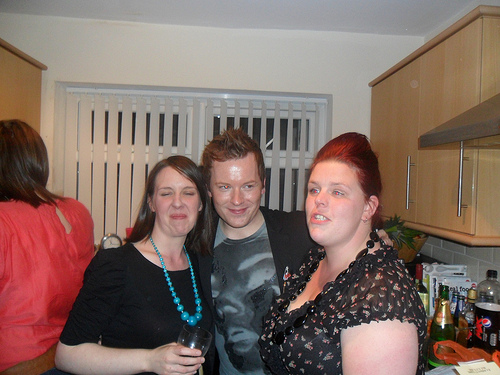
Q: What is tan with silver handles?
A: Cabinets.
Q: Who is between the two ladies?
A: Young man.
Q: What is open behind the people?
A: Blinds.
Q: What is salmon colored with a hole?
A: Blouse.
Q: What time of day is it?
A: Night.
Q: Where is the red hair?
A: On the woman.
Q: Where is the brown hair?
A: On the man.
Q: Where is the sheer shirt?
A: On the woman.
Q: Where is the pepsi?
A: On the counter.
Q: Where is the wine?
A: On the counter.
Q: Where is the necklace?
A: On the woman.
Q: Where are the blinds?
A: On the window.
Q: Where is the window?
A: In the wall.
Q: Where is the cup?
A: In her hand.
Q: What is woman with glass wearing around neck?
A: Blue beaded necklace.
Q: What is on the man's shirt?
A: Human face.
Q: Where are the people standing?
A: Kitchen.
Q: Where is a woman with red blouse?
A: Left side of picture.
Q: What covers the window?
A: White vertical blinds.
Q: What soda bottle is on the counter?
A: Pepsi max.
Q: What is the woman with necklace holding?
A: Glass.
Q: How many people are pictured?
A: Four.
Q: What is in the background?
A: A window.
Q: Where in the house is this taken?
A: The kitchen.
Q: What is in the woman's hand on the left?
A: A glass.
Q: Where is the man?
A: Between the two women.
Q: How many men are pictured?
A: One.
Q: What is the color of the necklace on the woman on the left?
A: Blue.